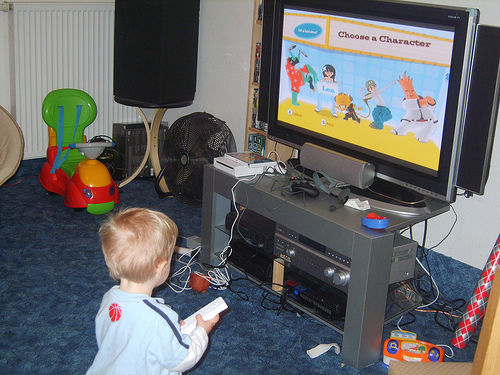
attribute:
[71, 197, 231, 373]
child — enjoying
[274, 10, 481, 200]
screen — TV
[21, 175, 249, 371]
child — entertaining